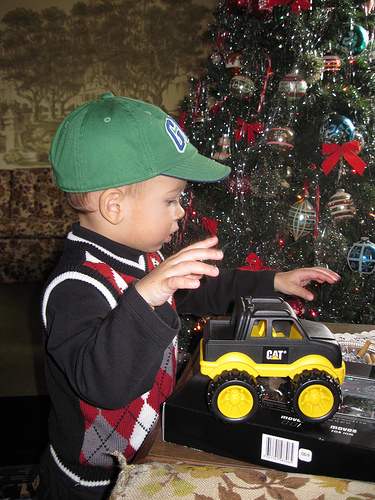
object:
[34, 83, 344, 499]
boy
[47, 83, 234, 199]
cap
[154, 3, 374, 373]
christmas tree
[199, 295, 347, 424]
toy truck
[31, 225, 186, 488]
sweater  vest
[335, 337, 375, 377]
ashtray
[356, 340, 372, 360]
cigarette butt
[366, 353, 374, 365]
cigarette butt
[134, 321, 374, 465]
table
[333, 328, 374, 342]
doily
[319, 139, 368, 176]
bow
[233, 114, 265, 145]
bow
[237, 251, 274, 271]
bow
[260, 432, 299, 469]
bar code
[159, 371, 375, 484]
box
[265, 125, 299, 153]
ornament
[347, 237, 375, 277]
ornament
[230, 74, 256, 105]
ornament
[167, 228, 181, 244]
mouth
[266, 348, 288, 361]
logo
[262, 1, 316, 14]
bow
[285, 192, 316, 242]
bulb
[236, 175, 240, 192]
tinsel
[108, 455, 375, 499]
sofa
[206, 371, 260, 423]
tire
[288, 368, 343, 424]
tire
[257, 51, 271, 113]
candy cane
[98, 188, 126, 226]
ear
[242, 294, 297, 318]
roof